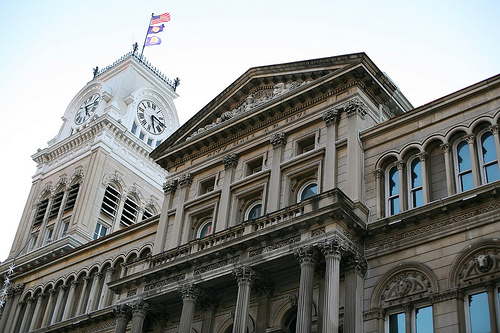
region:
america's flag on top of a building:
[138, 6, 173, 53]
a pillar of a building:
[323, 245, 339, 332]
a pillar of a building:
[291, 250, 313, 330]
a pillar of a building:
[174, 290, 196, 330]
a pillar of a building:
[226, 267, 249, 332]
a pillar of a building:
[130, 300, 146, 332]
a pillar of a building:
[111, 303, 124, 331]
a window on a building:
[381, 150, 430, 219]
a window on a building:
[378, 300, 437, 331]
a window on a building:
[451, 129, 495, 189]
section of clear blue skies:
[11, 10, 56, 27]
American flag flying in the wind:
[142, 10, 178, 22]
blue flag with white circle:
[137, 32, 177, 41]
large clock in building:
[131, 95, 177, 140]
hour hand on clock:
[145, 114, 172, 134]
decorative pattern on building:
[364, 263, 449, 300]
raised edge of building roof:
[167, 52, 395, 92]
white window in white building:
[95, 160, 146, 249]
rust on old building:
[299, 196, 340, 217]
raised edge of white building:
[117, 50, 192, 83]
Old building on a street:
[1, 41, 498, 329]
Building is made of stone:
[0, 42, 498, 330]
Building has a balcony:
[105, 192, 379, 303]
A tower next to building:
[12, 11, 194, 258]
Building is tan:
[1, 41, 498, 331]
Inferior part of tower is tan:
[4, 158, 165, 255]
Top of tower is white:
[37, 0, 187, 154]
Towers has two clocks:
[58, 81, 173, 138]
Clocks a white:
[60, 81, 171, 141]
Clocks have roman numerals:
[125, 7, 176, 61]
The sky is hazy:
[38, 21, 472, 142]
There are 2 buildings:
[60, 48, 443, 292]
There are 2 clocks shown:
[56, 71, 213, 163]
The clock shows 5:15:
[132, 71, 205, 215]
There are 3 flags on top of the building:
[133, 10, 212, 112]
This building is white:
[35, 18, 193, 245]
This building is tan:
[33, 80, 485, 322]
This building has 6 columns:
[89, 244, 424, 330]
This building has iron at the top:
[77, 38, 180, 164]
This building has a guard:
[99, 195, 378, 270]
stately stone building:
[26, 6, 471, 297]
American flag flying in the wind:
[95, 3, 177, 100]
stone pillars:
[225, 226, 362, 327]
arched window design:
[371, 141, 499, 190]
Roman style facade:
[150, 49, 400, 169]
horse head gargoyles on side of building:
[387, 269, 424, 302]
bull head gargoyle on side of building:
[467, 248, 497, 275]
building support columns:
[115, 247, 365, 327]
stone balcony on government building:
[111, 124, 378, 303]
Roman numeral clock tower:
[46, 60, 193, 153]